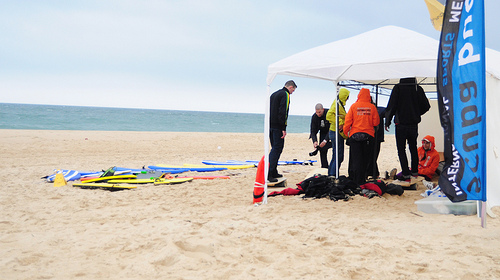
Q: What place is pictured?
A: It is a beach.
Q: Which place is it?
A: It is a beach.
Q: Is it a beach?
A: Yes, it is a beach.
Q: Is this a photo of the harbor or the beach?
A: It is showing the beach.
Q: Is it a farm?
A: No, it is a beach.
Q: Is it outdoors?
A: Yes, it is outdoors.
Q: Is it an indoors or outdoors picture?
A: It is outdoors.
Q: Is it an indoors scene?
A: No, it is outdoors.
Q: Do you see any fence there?
A: No, there are no fences.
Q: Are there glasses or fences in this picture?
A: No, there are no fences or glasses.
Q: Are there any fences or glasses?
A: No, there are no fences or glasses.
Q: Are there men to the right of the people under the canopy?
A: Yes, there is a man to the right of the people.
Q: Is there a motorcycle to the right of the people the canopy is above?
A: No, there is a man to the right of the people.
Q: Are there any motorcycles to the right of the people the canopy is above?
A: No, there is a man to the right of the people.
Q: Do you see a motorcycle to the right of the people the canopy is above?
A: No, there is a man to the right of the people.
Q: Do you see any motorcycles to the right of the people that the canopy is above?
A: No, there is a man to the right of the people.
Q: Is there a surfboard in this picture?
A: Yes, there is a surfboard.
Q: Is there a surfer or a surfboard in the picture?
A: Yes, there is a surfboard.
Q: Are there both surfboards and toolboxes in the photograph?
A: No, there is a surfboard but no toolboxes.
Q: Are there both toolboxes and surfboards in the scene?
A: No, there is a surfboard but no toolboxes.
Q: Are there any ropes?
A: No, there are no ropes.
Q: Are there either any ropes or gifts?
A: No, there are no ropes or gifts.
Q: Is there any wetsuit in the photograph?
A: Yes, there is a wetsuit.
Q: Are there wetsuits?
A: Yes, there is a wetsuit.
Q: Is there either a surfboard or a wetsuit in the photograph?
A: Yes, there is a wetsuit.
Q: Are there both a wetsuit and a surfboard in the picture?
A: Yes, there are both a wetsuit and a surfboard.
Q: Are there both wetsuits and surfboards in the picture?
A: Yes, there are both a wetsuit and a surfboard.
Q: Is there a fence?
A: No, there are no fences.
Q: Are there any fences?
A: No, there are no fences.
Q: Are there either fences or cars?
A: No, there are no fences or cars.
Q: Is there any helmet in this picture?
A: No, there are no helmets.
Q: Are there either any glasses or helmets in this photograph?
A: No, there are no helmets or glasses.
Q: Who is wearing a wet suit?
A: The man is wearing a wet suit.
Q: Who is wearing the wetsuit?
A: The man is wearing a wet suit.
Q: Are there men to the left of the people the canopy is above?
A: Yes, there is a man to the left of the people.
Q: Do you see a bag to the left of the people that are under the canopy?
A: No, there is a man to the left of the people.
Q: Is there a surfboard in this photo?
A: Yes, there is a surfboard.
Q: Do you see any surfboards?
A: Yes, there is a surfboard.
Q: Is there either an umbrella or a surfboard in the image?
A: Yes, there is a surfboard.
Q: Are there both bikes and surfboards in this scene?
A: No, there is a surfboard but no bikes.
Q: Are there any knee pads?
A: No, there are no knee pads.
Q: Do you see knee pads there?
A: No, there are no knee pads.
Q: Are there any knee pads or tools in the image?
A: No, there are no knee pads or tools.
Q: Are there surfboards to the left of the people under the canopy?
A: Yes, there is a surfboard to the left of the people.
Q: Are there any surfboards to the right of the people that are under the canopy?
A: No, the surfboard is to the left of the people.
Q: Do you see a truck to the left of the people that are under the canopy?
A: No, there is a surfboard to the left of the people.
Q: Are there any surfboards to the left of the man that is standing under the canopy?
A: Yes, there is a surfboard to the left of the man.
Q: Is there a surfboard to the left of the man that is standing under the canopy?
A: Yes, there is a surfboard to the left of the man.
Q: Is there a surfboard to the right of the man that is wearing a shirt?
A: No, the surfboard is to the left of the man.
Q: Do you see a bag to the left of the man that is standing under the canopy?
A: No, there is a surfboard to the left of the man.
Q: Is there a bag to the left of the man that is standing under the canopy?
A: No, there is a surfboard to the left of the man.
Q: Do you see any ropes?
A: No, there are no ropes.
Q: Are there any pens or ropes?
A: No, there are no ropes or pens.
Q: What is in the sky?
A: The clouds are in the sky.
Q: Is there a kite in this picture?
A: No, there are no kites.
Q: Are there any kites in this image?
A: No, there are no kites.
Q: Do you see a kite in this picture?
A: No, there are no kites.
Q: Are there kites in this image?
A: No, there are no kites.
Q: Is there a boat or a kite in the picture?
A: No, there are no kites or boats.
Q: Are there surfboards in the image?
A: Yes, there is a surfboard.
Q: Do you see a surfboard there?
A: Yes, there is a surfboard.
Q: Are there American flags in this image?
A: No, there are no American flags.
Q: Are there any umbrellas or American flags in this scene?
A: No, there are no American flags or umbrellas.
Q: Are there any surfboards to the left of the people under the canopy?
A: Yes, there is a surfboard to the left of the people.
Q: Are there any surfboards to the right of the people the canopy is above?
A: No, the surfboard is to the left of the people.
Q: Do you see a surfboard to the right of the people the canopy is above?
A: No, the surfboard is to the left of the people.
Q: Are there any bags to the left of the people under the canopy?
A: No, there is a surfboard to the left of the people.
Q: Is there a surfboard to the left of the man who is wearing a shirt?
A: Yes, there is a surfboard to the left of the man.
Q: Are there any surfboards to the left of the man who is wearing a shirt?
A: Yes, there is a surfboard to the left of the man.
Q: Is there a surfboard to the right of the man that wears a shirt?
A: No, the surfboard is to the left of the man.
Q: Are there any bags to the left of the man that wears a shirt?
A: No, there is a surfboard to the left of the man.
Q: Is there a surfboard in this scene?
A: Yes, there is a surfboard.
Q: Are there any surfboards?
A: Yes, there is a surfboard.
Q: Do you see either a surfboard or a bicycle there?
A: Yes, there is a surfboard.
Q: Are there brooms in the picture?
A: No, there are no brooms.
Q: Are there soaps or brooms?
A: No, there are no brooms or soaps.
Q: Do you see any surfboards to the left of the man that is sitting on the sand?
A: Yes, there is a surfboard to the left of the man.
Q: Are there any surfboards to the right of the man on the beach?
A: No, the surfboard is to the left of the man.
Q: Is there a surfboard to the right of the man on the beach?
A: No, the surfboard is to the left of the man.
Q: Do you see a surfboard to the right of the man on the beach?
A: No, the surfboard is to the left of the man.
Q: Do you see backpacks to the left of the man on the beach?
A: No, there is a surfboard to the left of the man.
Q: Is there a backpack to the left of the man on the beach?
A: No, there is a surfboard to the left of the man.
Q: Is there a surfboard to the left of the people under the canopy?
A: Yes, there is a surfboard to the left of the people.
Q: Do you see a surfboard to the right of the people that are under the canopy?
A: No, the surfboard is to the left of the people.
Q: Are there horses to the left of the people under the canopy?
A: No, there is a surfboard to the left of the people.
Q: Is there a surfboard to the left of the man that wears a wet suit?
A: Yes, there is a surfboard to the left of the man.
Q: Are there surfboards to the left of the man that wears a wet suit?
A: Yes, there is a surfboard to the left of the man.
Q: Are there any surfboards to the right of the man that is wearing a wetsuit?
A: No, the surfboard is to the left of the man.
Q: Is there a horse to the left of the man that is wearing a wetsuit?
A: No, there is a surfboard to the left of the man.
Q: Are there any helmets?
A: No, there are no helmets.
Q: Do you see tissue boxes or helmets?
A: No, there are no helmets or tissue boxes.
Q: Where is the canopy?
A: The canopy is on the beach.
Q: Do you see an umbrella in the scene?
A: No, there are no umbrellas.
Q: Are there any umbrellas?
A: No, there are no umbrellas.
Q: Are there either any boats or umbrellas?
A: No, there are no umbrellas or boats.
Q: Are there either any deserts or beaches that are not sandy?
A: No, there is a beach but it is sandy.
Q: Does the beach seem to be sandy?
A: Yes, the beach is sandy.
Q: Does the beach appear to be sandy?
A: Yes, the beach is sandy.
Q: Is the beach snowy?
A: No, the beach is sandy.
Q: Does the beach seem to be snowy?
A: No, the beach is sandy.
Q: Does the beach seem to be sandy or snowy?
A: The beach is sandy.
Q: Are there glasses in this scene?
A: No, there are no glasses.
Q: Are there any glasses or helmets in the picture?
A: No, there are no glasses or helmets.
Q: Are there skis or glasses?
A: No, there are no glasses or skis.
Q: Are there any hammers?
A: No, there are no hammers.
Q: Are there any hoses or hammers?
A: No, there are no hammers or hoses.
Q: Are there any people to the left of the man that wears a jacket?
A: Yes, there are people to the left of the man.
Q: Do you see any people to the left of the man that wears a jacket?
A: Yes, there are people to the left of the man.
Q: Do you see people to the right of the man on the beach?
A: No, the people are to the left of the man.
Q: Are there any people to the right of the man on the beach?
A: No, the people are to the left of the man.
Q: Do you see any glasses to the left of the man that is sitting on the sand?
A: No, there are people to the left of the man.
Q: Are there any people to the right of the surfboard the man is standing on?
A: Yes, there are people to the right of the surfboard.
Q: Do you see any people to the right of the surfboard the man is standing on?
A: Yes, there are people to the right of the surfboard.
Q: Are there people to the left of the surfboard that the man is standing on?
A: No, the people are to the right of the surf board.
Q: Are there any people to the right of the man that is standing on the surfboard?
A: Yes, there are people to the right of the man.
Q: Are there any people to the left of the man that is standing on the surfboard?
A: No, the people are to the right of the man.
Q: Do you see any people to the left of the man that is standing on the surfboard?
A: No, the people are to the right of the man.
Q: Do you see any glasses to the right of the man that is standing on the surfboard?
A: No, there are people to the right of the man.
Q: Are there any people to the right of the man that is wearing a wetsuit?
A: Yes, there are people to the right of the man.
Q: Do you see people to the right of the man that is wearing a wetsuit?
A: Yes, there are people to the right of the man.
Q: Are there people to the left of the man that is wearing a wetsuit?
A: No, the people are to the right of the man.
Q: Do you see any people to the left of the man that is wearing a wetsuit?
A: No, the people are to the right of the man.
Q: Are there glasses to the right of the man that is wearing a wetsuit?
A: No, there are people to the right of the man.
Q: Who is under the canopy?
A: The people are under the canopy.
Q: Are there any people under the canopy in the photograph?
A: Yes, there are people under the canopy.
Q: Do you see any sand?
A: Yes, there is sand.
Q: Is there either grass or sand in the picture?
A: Yes, there is sand.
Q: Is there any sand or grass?
A: Yes, there is sand.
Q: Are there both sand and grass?
A: No, there is sand but no grass.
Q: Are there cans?
A: No, there are no cans.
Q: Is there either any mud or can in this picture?
A: No, there are no cans or mud.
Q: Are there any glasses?
A: No, there are no glasses.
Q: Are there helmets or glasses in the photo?
A: No, there are no glasses or helmets.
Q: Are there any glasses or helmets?
A: No, there are no glasses or helmets.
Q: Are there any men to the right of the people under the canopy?
A: Yes, there is a man to the right of the people.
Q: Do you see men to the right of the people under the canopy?
A: Yes, there is a man to the right of the people.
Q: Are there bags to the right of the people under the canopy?
A: No, there is a man to the right of the people.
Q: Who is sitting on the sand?
A: The man is sitting on the sand.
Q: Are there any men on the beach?
A: Yes, there is a man on the beach.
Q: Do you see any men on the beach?
A: Yes, there is a man on the beach.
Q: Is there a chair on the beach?
A: No, there is a man on the beach.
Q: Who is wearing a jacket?
A: The man is wearing a jacket.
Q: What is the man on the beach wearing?
A: The man is wearing a jacket.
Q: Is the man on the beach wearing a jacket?
A: Yes, the man is wearing a jacket.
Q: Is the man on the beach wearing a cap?
A: No, the man is wearing a jacket.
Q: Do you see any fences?
A: No, there are no fences.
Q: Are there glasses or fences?
A: No, there are no fences or glasses.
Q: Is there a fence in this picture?
A: No, there are no fences.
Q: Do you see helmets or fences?
A: No, there are no fences or helmets.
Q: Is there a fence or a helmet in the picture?
A: No, there are no fences or helmets.